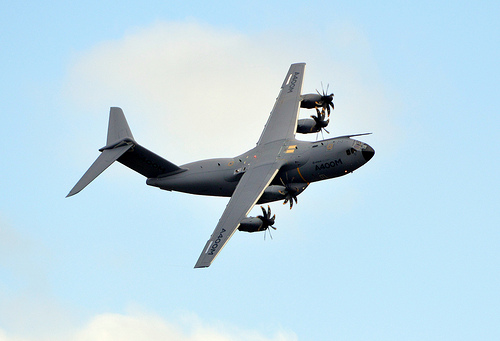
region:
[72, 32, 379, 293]
gray airplane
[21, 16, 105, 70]
white clouds in blue sky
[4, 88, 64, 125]
white clouds in blue sky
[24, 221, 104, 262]
white clouds in blue sky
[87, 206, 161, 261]
white clouds in blue sky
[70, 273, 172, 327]
white clouds in blue sky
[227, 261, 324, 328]
white clouds in blue sky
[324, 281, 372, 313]
white clouds in blue sky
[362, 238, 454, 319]
white clouds in blue sky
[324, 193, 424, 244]
white clouds in blue sky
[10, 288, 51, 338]
Part of a light blue sky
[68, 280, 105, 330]
Part of a light blue sky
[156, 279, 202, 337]
Part of a light blue sky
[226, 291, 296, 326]
Part of a light blue sky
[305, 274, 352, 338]
Part of a light blue sky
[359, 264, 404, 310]
Part of a light blue sky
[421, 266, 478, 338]
Part of a light blue sky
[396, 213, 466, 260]
Part of a light blue sky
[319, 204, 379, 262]
Part of a light blue sky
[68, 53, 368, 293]
Dull grey air plane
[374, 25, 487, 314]
The sky is clear and blue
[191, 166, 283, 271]
The wing of the airplane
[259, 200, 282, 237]
The propeller on the airplane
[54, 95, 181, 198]
The tail of the plane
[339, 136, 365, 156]
The cockpit of the plane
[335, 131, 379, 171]
The nose of the plane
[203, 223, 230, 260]
The identifying mark of the airplane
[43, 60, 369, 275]
The airplane is the color gray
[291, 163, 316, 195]
The stripe is the color yellow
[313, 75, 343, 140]
The propellers are the color black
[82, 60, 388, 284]
gray airplane in air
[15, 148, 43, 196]
white clouds in blue sky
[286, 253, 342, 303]
white clouds in blue sky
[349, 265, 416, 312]
white clouds in blue sky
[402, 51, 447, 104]
white clouds in blue sky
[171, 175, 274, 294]
wing of the plane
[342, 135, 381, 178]
nose of the plane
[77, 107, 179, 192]
tail of the plane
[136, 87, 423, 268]
black plane in the air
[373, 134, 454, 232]
blue sky behind the plane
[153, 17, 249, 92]
cloud in the sky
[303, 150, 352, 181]
black writing on the plane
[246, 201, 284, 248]
propellor on the plane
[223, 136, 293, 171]
top of the plane